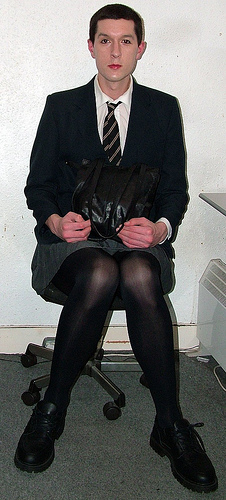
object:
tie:
[102, 100, 124, 173]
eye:
[99, 37, 110, 49]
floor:
[0, 352, 226, 497]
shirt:
[91, 72, 134, 170]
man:
[13, 2, 220, 490]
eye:
[121, 36, 132, 47]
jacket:
[24, 74, 189, 263]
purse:
[68, 156, 160, 244]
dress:
[30, 235, 176, 308]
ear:
[135, 39, 147, 65]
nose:
[111, 43, 120, 58]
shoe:
[13, 395, 66, 472]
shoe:
[148, 413, 218, 493]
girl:
[13, 4, 218, 489]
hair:
[89, 3, 142, 47]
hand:
[117, 215, 158, 249]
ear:
[87, 35, 97, 60]